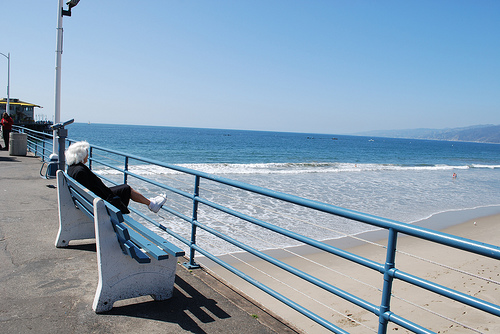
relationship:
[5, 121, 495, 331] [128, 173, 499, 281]
railing by beach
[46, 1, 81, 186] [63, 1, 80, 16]
pole for light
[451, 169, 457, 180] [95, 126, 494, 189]
someone in ocean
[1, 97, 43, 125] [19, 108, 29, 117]
building has a part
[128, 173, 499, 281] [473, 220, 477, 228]
beach has a sea gull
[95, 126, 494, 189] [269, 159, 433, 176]
ocean has waves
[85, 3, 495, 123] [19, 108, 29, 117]
sky has a part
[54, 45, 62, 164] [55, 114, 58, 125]
metal has a part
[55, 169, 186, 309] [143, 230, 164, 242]
bench has a part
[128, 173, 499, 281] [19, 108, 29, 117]
beach has a part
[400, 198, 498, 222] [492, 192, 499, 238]
shore has an edge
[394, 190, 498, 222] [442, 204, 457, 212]
water has a part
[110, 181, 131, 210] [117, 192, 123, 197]
skirt has a part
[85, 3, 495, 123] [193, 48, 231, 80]
sky has a part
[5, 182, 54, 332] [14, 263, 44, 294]
floor has a part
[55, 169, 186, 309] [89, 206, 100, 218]
bench has a part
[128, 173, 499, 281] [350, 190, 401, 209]
beach has a part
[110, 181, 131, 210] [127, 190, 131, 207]
skirt has an edge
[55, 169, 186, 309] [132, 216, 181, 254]
bench has an edge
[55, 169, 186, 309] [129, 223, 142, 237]
bench has a part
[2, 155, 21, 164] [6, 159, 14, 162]
shade has a part